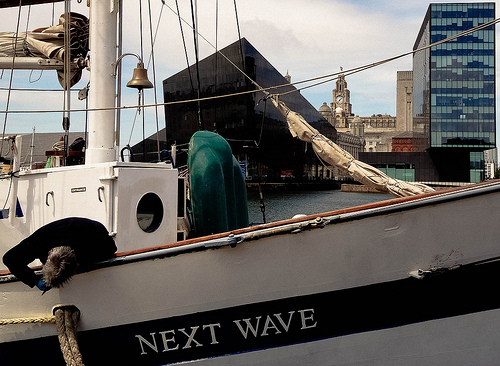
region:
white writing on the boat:
[115, 293, 347, 365]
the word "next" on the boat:
[136, 313, 226, 361]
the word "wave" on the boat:
[224, 283, 331, 346]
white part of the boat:
[257, 234, 339, 285]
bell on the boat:
[117, 59, 159, 108]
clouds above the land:
[286, 12, 338, 50]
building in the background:
[314, 73, 371, 122]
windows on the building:
[438, 48, 485, 108]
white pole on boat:
[66, 9, 151, 145]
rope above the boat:
[173, 38, 436, 131]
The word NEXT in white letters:
[133, 320, 225, 355]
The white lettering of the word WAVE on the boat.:
[231, 308, 318, 338]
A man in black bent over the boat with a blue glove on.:
[1, 216, 117, 293]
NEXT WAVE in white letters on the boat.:
[136, 307, 317, 354]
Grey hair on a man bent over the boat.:
[38, 245, 80, 290]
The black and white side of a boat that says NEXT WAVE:
[0, 183, 499, 365]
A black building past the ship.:
[161, 35, 337, 177]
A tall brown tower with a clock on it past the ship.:
[331, 63, 353, 127]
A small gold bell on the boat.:
[126, 58, 153, 90]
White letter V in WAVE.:
[272, 309, 295, 333]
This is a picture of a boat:
[153, 216, 379, 337]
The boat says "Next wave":
[133, 299, 348, 364]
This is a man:
[33, 204, 175, 346]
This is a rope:
[38, 315, 85, 360]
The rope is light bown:
[51, 321, 86, 349]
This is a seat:
[189, 155, 261, 216]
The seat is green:
[184, 161, 296, 241]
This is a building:
[311, 41, 378, 146]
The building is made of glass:
[431, 15, 473, 160]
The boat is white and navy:
[301, 230, 385, 354]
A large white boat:
[0, 174, 498, 364]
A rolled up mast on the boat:
[267, 90, 433, 200]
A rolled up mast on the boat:
[0, 10, 85, 65]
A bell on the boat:
[111, 50, 147, 112]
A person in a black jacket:
[5, 215, 115, 292]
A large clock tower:
[330, 65, 350, 115]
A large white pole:
[83, 0, 123, 162]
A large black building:
[160, 35, 333, 175]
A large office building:
[412, 2, 492, 147]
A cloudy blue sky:
[2, 1, 499, 162]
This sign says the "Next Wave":
[140, 298, 285, 364]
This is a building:
[384, 55, 476, 123]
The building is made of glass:
[426, 54, 469, 102]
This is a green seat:
[168, 117, 279, 282]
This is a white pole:
[66, 95, 125, 189]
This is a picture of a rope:
[55, 312, 97, 363]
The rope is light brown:
[31, 298, 95, 363]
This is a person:
[36, 227, 95, 279]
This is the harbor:
[313, 186, 377, 226]